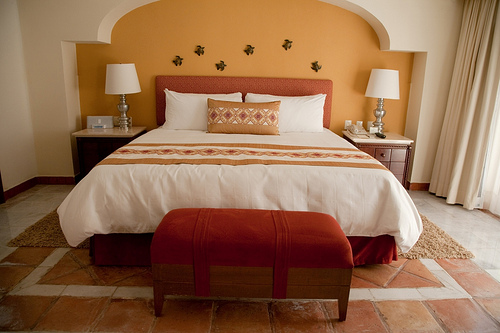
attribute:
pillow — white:
[154, 78, 244, 137]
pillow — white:
[241, 91, 328, 140]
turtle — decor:
[168, 51, 185, 67]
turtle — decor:
[192, 41, 207, 58]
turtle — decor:
[208, 56, 231, 73]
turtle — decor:
[240, 40, 261, 60]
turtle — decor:
[280, 37, 296, 56]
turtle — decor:
[306, 58, 326, 77]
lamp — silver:
[102, 59, 143, 133]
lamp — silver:
[358, 61, 405, 132]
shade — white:
[99, 59, 142, 103]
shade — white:
[360, 65, 405, 112]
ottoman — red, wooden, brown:
[112, 205, 366, 320]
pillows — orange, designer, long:
[206, 92, 289, 139]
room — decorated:
[1, 10, 497, 331]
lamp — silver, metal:
[364, 67, 415, 143]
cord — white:
[341, 135, 372, 145]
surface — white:
[345, 126, 416, 149]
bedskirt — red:
[347, 237, 407, 272]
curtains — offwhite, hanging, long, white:
[425, 1, 479, 213]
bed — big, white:
[52, 66, 403, 253]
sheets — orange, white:
[125, 126, 330, 212]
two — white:
[169, 96, 340, 134]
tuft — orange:
[85, 239, 142, 275]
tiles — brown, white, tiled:
[385, 260, 482, 332]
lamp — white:
[93, 60, 143, 100]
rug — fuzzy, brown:
[424, 230, 464, 257]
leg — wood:
[133, 293, 170, 328]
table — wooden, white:
[350, 149, 416, 206]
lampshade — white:
[347, 67, 409, 104]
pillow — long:
[151, 87, 247, 130]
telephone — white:
[346, 122, 372, 141]